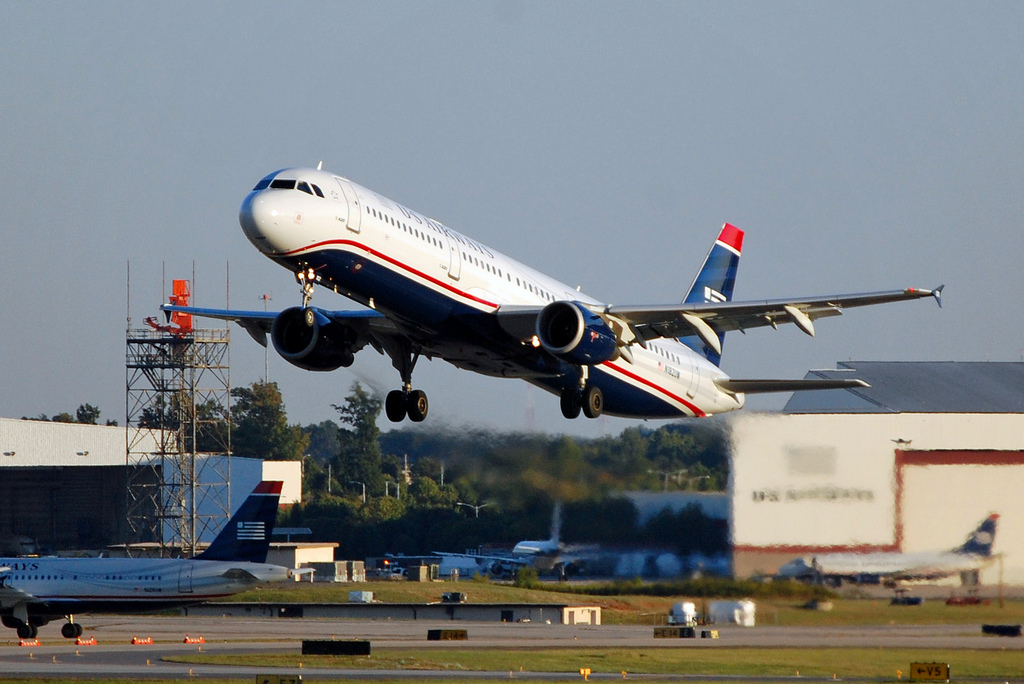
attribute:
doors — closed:
[332, 178, 367, 231]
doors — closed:
[438, 223, 471, 288]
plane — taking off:
[161, 155, 948, 421]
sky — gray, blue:
[5, 3, 1023, 438]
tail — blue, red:
[671, 222, 747, 361]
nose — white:
[239, 155, 324, 259]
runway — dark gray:
[1, 615, 1021, 654]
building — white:
[733, 358, 1021, 579]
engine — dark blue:
[530, 297, 623, 367]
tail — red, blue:
[662, 220, 745, 359]